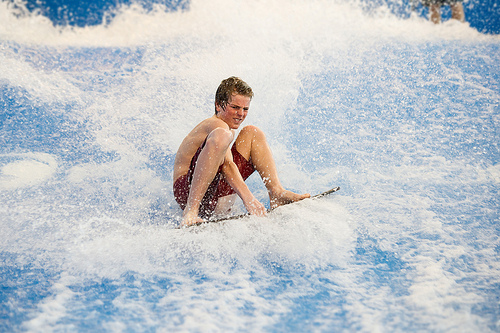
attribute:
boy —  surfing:
[139, 72, 314, 227]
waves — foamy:
[0, 0, 499, 331]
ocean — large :
[31, 25, 178, 299]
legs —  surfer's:
[423, 1, 478, 28]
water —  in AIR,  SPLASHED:
[9, 17, 165, 248]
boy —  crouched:
[150, 52, 320, 228]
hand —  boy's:
[243, 196, 266, 216]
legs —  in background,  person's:
[422, 0, 472, 27]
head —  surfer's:
[215, 77, 252, 128]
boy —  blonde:
[167, 77, 307, 222]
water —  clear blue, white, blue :
[1, 5, 488, 327]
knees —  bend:
[211, 125, 290, 155]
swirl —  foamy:
[2, 117, 87, 219]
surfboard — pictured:
[198, 201, 300, 226]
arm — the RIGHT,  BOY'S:
[216, 119, 267, 220]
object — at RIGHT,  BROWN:
[424, 0, 466, 28]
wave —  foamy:
[71, 225, 361, 266]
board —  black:
[151, 181, 341, 234]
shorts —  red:
[173, 143, 253, 217]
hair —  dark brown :
[213, 75, 253, 114]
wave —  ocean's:
[0, 7, 175, 274]